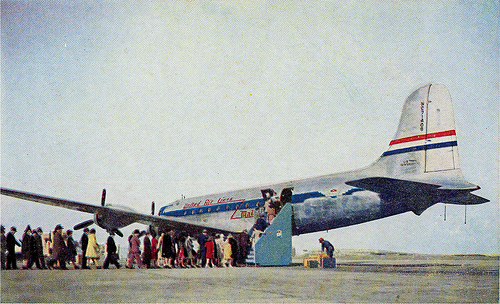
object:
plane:
[0, 80, 491, 245]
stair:
[242, 202, 293, 266]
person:
[219, 236, 235, 268]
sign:
[276, 229, 282, 238]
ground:
[0, 259, 500, 303]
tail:
[364, 83, 460, 170]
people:
[4, 225, 24, 270]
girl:
[84, 227, 102, 269]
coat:
[84, 233, 102, 260]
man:
[196, 228, 210, 268]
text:
[183, 197, 265, 220]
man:
[318, 237, 336, 258]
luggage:
[319, 257, 337, 269]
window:
[225, 204, 229, 210]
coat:
[204, 240, 215, 259]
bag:
[307, 259, 319, 269]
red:
[329, 188, 338, 192]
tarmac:
[0, 259, 500, 303]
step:
[246, 250, 250, 254]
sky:
[0, 0, 500, 256]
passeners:
[266, 203, 276, 224]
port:
[0, 83, 479, 237]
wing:
[0, 185, 243, 238]